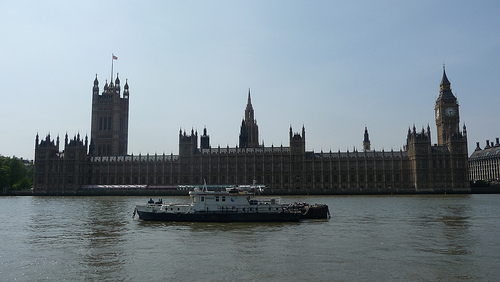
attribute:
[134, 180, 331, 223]
boat — white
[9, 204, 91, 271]
river — calm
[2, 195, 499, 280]
water — green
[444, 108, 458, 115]
face — white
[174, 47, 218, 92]
cloud — white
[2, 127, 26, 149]
cloud — white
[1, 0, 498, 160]
sky — blue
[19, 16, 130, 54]
white clouds — white 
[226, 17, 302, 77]
cloud — white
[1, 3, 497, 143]
sky — blue